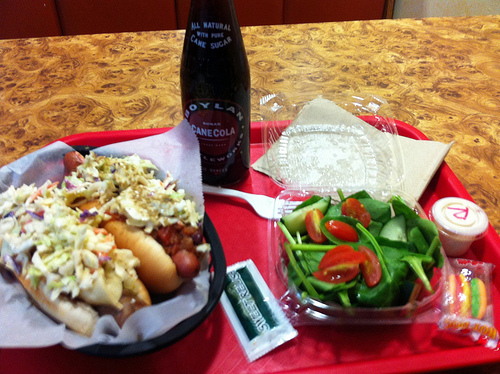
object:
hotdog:
[60, 143, 206, 296]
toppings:
[76, 152, 195, 223]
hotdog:
[0, 183, 138, 335]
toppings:
[7, 191, 116, 296]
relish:
[212, 257, 295, 366]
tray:
[0, 111, 485, 374]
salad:
[282, 195, 432, 298]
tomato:
[303, 207, 331, 244]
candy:
[448, 268, 486, 326]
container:
[426, 195, 489, 259]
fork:
[197, 181, 301, 220]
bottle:
[176, 1, 254, 192]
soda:
[181, 57, 249, 190]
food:
[0, 158, 198, 330]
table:
[4, 20, 499, 374]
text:
[190, 20, 232, 32]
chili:
[157, 224, 179, 255]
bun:
[105, 218, 186, 295]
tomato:
[313, 245, 366, 282]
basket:
[81, 210, 229, 362]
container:
[253, 89, 453, 331]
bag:
[433, 256, 498, 351]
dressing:
[427, 195, 491, 258]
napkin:
[250, 92, 456, 208]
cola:
[213, 126, 237, 137]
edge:
[0, 27, 183, 42]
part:
[52, 68, 97, 91]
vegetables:
[374, 221, 412, 257]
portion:
[158, 243, 203, 286]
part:
[191, 5, 234, 20]